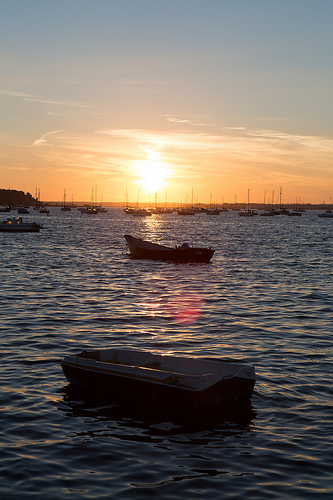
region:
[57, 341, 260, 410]
The boat nearest the camera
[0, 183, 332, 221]
The sailboats in the background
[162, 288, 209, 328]
The red lense flare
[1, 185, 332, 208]
The horizon line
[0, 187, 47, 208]
The hill on the left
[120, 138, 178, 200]
The sun that's about to set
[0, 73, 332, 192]
The clouds in the sky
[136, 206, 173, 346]
The sun reflecting off the water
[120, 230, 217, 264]
The boat interrupting the sun's reflection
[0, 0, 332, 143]
The blue sky above the clouds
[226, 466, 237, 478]
the water is clear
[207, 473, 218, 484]
the water is clear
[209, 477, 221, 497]
the water is clear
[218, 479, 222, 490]
the water is clear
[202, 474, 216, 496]
the water is clear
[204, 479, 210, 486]
the water is clear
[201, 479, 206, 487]
the water is clear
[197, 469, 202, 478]
the water is clear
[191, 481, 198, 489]
the water is clear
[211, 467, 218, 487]
the water is clear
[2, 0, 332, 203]
an orange sunset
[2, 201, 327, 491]
a blue body of water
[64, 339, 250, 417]
a small white boat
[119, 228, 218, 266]
a small silhouetted boat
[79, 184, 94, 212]
sail boat in distance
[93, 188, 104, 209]
sail boat in distance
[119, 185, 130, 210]
sail boat in distance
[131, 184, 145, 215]
sail boat in distance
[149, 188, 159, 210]
sail boat in distance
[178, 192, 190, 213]
sail boat in distance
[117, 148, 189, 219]
sun setting over boats on the water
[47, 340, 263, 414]
boat floating on the water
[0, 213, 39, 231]
lights on inside the cabin of the boat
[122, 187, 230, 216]
sailboats with sails down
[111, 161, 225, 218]
sun setting over sailboats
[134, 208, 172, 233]
reflection of the sun on the water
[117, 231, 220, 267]
boat floating on the water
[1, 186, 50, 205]
hill in the background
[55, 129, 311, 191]
clouds lit up by sun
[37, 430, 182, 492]
small waves in the water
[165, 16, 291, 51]
The sky is blue.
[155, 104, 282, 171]
A few clouds are in the sky.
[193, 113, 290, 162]
The clouds are white.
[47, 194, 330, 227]
Boats are in the water.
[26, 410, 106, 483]
Waves are in the water.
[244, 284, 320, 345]
The water is blue.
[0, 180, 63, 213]
A hill is in the background.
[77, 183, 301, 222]
The boats have their sails down.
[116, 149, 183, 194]
The sun is in the sky.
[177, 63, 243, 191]
The sky is changing color.